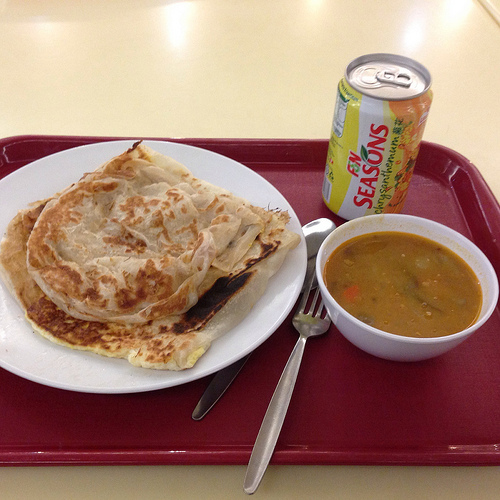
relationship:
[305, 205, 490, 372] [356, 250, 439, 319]
bowl with soup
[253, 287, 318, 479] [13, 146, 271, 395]
fork between plate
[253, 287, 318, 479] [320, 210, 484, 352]
fork between bowl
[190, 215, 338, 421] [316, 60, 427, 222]
fork near can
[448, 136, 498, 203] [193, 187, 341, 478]
tray with utensils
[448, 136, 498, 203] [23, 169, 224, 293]
tray with food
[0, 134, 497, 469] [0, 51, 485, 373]
tray full of food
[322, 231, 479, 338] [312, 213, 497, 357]
soup in bowl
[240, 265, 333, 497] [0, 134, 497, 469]
fork on tray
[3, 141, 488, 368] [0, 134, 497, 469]
food on tray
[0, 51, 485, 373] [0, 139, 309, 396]
food on plate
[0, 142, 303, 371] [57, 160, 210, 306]
bread probably pancakes